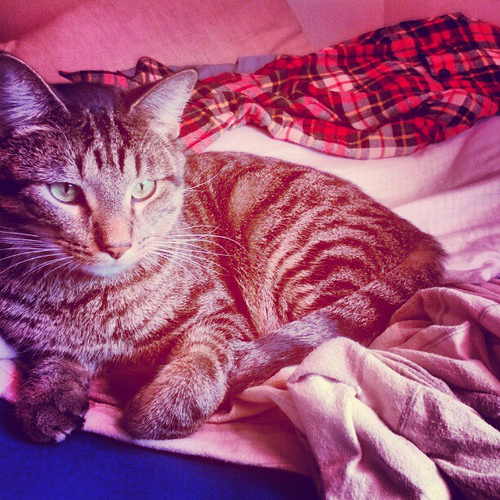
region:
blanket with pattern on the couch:
[223, 12, 493, 147]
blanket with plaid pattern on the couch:
[249, 7, 481, 143]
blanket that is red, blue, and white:
[263, 14, 473, 144]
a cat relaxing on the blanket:
[4, 55, 434, 435]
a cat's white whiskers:
[161, 228, 235, 276]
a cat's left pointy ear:
[130, 67, 200, 133]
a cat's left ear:
[136, 67, 198, 129]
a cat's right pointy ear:
[3, 47, 75, 129]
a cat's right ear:
[0, 51, 57, 117]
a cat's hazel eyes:
[129, 177, 159, 201]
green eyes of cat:
[37, 148, 169, 214]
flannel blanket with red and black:
[221, 48, 459, 147]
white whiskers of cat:
[9, 230, 241, 282]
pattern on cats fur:
[242, 181, 375, 306]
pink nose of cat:
[102, 235, 140, 262]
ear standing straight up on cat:
[110, 63, 245, 155]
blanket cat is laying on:
[272, 350, 494, 472]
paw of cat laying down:
[17, 368, 117, 459]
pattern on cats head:
[82, 132, 148, 191]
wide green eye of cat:
[49, 177, 88, 212]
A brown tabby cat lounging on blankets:
[1, 45, 454, 451]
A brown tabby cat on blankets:
[3, 49, 455, 453]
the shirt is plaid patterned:
[56, 2, 496, 162]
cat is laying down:
[0, 37, 453, 451]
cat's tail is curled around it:
[198, 237, 442, 397]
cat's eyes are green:
[38, 170, 165, 211]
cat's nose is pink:
[104, 244, 138, 262]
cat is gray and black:
[0, 39, 448, 443]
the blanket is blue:
[1, 397, 330, 497]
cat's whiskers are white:
[1, 212, 244, 268]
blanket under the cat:
[192, 285, 498, 495]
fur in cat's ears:
[1, 59, 198, 140]